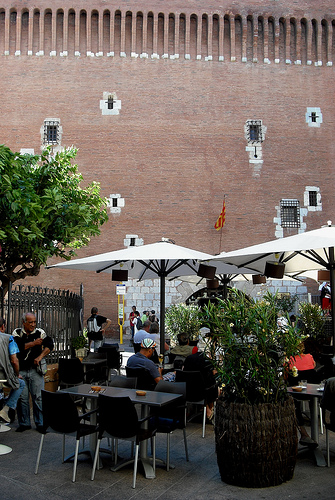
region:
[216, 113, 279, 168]
a window on a building.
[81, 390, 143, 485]
a chair at a table.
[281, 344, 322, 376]
an orange object.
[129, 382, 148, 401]
a bowl on a table.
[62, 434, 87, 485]
a metal leg on a chair.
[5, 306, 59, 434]
a man wearing blue jeans.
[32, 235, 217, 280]
a white table umbrella.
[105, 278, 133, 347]
a sign on a pole.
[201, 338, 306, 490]
a plant in a barrel.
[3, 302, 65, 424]
a man in a shirt.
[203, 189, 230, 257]
A striped yellow and red flag.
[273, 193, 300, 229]
A small window with bars on it.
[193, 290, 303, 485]
A small tree.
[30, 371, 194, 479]
A black table with chairs.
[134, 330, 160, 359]
The man is wearing a hat.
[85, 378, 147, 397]
Ashtrays on the table.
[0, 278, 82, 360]
A metal fence.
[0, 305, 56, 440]
The two men are talking.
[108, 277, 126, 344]
A sign.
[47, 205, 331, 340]
Two large white umbrellas.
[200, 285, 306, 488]
tall green plant in brown basket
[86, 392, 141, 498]
black and silver chair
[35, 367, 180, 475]
four chairs and a table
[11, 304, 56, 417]
older man standing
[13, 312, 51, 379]
man in black and white jacket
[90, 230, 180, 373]
white umbrella with lights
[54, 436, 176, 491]
table legs and chair legs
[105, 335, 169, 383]
man wearing a hat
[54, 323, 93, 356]
a small green plant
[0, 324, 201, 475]
people at a restuarant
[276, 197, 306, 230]
A window on the building with bars.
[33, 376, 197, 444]
A empty black table.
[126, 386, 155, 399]
A brown ash tray.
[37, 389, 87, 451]
Black chairs at the table.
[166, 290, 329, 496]
A great big plant for decoration.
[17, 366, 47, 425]
A man wears grey jeans.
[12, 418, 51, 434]
A man wears black shoes.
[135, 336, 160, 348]
A man wears a red, white, and blue baseball cap.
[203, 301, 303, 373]
The green leaf's of the plant.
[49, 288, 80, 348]
Black gate surrounding a nearby building.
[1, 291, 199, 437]
A crowd of people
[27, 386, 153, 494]
Chairs are black and silver in color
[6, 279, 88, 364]
A silver fence is in the background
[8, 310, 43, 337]
Older man has gray hair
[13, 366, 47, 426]
Older man is wearing blue jeans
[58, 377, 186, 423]
Table is dark gray in color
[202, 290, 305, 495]
A plant is in the foreground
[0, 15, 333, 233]
A large brick wall is in the background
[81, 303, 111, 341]
Person in the background has a black shirt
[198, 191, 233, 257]
A red and yellow flag is in the background